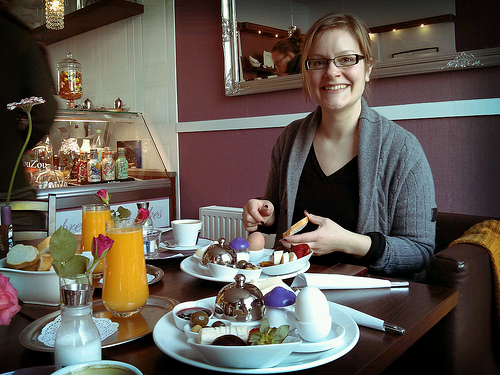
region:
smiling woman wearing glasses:
[304, 53, 366, 75]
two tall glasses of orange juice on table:
[78, 201, 159, 324]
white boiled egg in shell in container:
[292, 286, 332, 335]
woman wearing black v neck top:
[288, 151, 359, 251]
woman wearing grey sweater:
[257, 100, 446, 270]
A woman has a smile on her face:
[295, 7, 380, 114]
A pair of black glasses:
[300, 46, 366, 72]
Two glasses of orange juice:
[72, 195, 152, 321]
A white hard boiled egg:
[290, 280, 330, 321]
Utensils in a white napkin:
[300, 265, 411, 290]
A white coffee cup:
[165, 211, 205, 247]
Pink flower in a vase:
[41, 220, 118, 367]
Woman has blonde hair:
[295, 6, 377, 116]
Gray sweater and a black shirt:
[260, 92, 440, 279]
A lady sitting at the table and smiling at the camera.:
[240, 11, 436, 272]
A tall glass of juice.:
[100, 210, 152, 317]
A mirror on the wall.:
[370, 0, 497, 75]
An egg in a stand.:
[290, 284, 331, 336]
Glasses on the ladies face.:
[301, 52, 375, 73]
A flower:
[7, 94, 45, 209]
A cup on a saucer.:
[170, 216, 202, 251]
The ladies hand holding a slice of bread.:
[278, 210, 337, 257]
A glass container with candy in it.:
[57, 48, 82, 104]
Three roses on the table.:
[84, 183, 151, 277]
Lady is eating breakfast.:
[241, 16, 436, 271]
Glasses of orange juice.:
[78, 203, 152, 318]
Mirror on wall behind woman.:
[219, 5, 499, 100]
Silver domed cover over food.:
[210, 268, 268, 320]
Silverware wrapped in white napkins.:
[302, 268, 414, 333]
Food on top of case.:
[22, 120, 138, 191]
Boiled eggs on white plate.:
[154, 281, 361, 367]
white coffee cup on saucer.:
[158, 215, 212, 255]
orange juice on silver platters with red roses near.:
[78, 187, 156, 324]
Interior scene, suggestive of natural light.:
[4, 1, 499, 373]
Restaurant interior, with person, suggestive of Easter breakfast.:
[2, 5, 496, 374]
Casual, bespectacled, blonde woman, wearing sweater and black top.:
[247, 17, 432, 276]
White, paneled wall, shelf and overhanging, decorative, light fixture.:
[41, 3, 181, 52]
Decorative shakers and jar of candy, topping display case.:
[56, 53, 133, 118]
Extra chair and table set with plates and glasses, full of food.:
[6, 199, 431, 372]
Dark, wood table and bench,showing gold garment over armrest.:
[420, 219, 497, 371]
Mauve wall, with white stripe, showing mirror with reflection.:
[191, 0, 498, 136]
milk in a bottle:
[59, 330, 90, 356]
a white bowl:
[244, 345, 264, 360]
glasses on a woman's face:
[305, 50, 365, 72]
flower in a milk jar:
[41, 225, 116, 284]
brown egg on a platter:
[242, 229, 268, 252]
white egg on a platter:
[294, 283, 329, 325]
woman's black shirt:
[287, 134, 366, 254]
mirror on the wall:
[214, 0, 499, 97]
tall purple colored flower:
[4, 90, 48, 203]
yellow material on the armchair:
[445, 212, 499, 282]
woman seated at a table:
[237, 6, 448, 285]